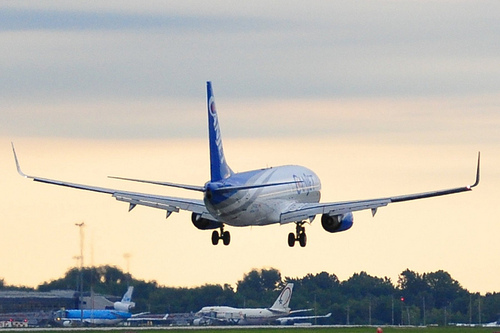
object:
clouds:
[0, 0, 496, 164]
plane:
[53, 46, 483, 278]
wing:
[7, 141, 202, 222]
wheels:
[285, 232, 295, 248]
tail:
[204, 79, 234, 182]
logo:
[292, 172, 323, 196]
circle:
[278, 286, 292, 308]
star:
[277, 298, 284, 304]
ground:
[0, 322, 500, 333]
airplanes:
[192, 281, 316, 326]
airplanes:
[49, 300, 153, 328]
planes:
[7, 78, 482, 249]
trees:
[483, 291, 500, 333]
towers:
[70, 219, 94, 275]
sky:
[0, 0, 499, 287]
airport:
[0, 253, 500, 332]